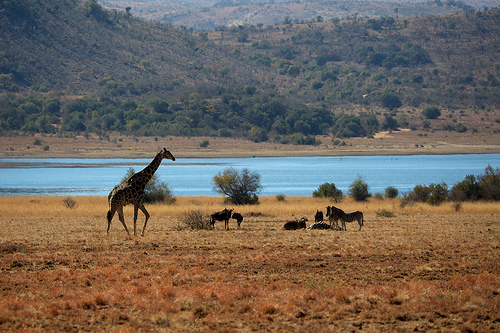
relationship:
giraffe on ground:
[103, 144, 176, 239] [0, 192, 497, 331]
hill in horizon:
[4, 3, 499, 134] [0, 1, 498, 198]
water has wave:
[0, 157, 492, 194] [2, 155, 238, 166]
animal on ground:
[230, 211, 247, 231] [0, 192, 497, 331]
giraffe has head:
[103, 144, 176, 239] [162, 145, 178, 161]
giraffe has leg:
[103, 144, 176, 239] [138, 201, 150, 235]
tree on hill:
[245, 103, 277, 140] [4, 3, 499, 134]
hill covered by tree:
[4, 3, 499, 134] [245, 103, 277, 140]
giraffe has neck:
[103, 144, 176, 239] [144, 154, 164, 188]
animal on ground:
[312, 216, 346, 235] [0, 192, 497, 331]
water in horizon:
[0, 157, 492, 194] [0, 1, 498, 198]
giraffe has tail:
[103, 144, 176, 239] [103, 192, 116, 228]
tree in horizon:
[245, 103, 277, 140] [0, 1, 498, 198]